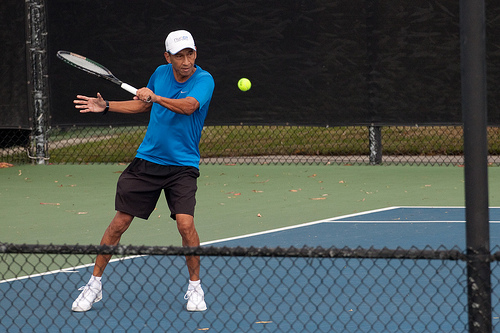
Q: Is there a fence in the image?
A: Yes, there is a fence.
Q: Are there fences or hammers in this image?
A: Yes, there is a fence.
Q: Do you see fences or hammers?
A: Yes, there is a fence.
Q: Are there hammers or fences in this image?
A: Yes, there is a fence.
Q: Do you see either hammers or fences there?
A: Yes, there is a fence.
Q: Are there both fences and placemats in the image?
A: No, there is a fence but no placemats.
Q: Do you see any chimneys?
A: No, there are no chimneys.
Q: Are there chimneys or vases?
A: No, there are no chimneys or vases.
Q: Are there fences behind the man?
A: Yes, there is a fence behind the man.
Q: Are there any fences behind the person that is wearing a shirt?
A: Yes, there is a fence behind the man.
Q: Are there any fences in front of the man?
A: No, the fence is behind the man.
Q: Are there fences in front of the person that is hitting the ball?
A: No, the fence is behind the man.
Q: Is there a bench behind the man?
A: No, there is a fence behind the man.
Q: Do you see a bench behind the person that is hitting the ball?
A: No, there is a fence behind the man.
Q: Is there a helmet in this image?
A: No, there are no helmets.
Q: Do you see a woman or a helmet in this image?
A: No, there are no helmets or women.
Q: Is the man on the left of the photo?
A: Yes, the man is on the left of the image.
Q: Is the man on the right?
A: No, the man is on the left of the image.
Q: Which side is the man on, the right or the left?
A: The man is on the left of the image.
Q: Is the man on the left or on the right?
A: The man is on the left of the image.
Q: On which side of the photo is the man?
A: The man is on the left of the image.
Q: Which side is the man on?
A: The man is on the left of the image.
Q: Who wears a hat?
A: The man wears a hat.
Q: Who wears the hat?
A: The man wears a hat.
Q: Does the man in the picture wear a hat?
A: Yes, the man wears a hat.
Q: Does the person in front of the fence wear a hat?
A: Yes, the man wears a hat.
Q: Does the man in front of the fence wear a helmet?
A: No, the man wears a hat.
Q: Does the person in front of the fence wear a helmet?
A: No, the man wears a hat.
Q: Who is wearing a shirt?
A: The man is wearing a shirt.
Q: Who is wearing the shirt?
A: The man is wearing a shirt.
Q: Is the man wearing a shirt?
A: Yes, the man is wearing a shirt.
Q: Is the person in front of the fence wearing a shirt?
A: Yes, the man is wearing a shirt.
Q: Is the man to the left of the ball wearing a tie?
A: No, the man is wearing a shirt.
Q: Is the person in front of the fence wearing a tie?
A: No, the man is wearing a shirt.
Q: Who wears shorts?
A: The man wears shorts.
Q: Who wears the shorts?
A: The man wears shorts.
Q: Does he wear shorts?
A: Yes, the man wears shorts.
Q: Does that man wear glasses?
A: No, the man wears shorts.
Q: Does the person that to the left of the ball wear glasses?
A: No, the man wears shorts.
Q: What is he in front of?
A: The man is in front of the fence.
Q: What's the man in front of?
A: The man is in front of the fence.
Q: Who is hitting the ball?
A: The man is hitting the ball.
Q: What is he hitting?
A: The man is hitting the ball.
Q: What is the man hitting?
A: The man is hitting the ball.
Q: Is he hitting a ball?
A: Yes, the man is hitting a ball.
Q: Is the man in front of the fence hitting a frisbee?
A: No, the man is hitting a ball.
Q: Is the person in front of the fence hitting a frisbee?
A: No, the man is hitting a ball.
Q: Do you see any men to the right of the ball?
A: No, the man is to the left of the ball.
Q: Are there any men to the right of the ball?
A: No, the man is to the left of the ball.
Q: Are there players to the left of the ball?
A: No, there is a man to the left of the ball.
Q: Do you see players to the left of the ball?
A: No, there is a man to the left of the ball.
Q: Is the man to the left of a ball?
A: Yes, the man is to the left of a ball.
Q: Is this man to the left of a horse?
A: No, the man is to the left of a ball.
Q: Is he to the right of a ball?
A: No, the man is to the left of a ball.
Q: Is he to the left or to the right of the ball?
A: The man is to the left of the ball.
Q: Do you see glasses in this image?
A: No, there are no glasses.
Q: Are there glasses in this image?
A: No, there are no glasses.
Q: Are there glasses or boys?
A: No, there are no glasses or boys.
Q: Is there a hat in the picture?
A: Yes, there is a hat.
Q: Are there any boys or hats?
A: Yes, there is a hat.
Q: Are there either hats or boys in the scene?
A: Yes, there is a hat.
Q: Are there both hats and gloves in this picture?
A: No, there is a hat but no gloves.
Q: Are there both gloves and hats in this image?
A: No, there is a hat but no gloves.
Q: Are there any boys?
A: No, there are no boys.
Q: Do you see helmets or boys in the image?
A: No, there are no boys or helmets.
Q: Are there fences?
A: Yes, there is a fence.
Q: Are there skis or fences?
A: Yes, there is a fence.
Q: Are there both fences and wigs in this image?
A: No, there is a fence but no wigs.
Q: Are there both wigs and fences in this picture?
A: No, there is a fence but no wigs.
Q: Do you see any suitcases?
A: No, there are no suitcases.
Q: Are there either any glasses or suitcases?
A: No, there are no suitcases or glasses.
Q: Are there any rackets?
A: Yes, there is a racket.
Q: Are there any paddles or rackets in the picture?
A: Yes, there is a racket.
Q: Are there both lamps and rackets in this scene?
A: No, there is a racket but no lamps.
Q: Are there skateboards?
A: No, there are no skateboards.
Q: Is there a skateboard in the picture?
A: No, there are no skateboards.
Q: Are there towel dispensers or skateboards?
A: No, there are no skateboards or towel dispensers.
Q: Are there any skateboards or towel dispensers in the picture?
A: No, there are no skateboards or towel dispensers.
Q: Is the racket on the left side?
A: Yes, the racket is on the left of the image.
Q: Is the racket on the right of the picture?
A: No, the racket is on the left of the image.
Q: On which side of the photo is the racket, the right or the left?
A: The racket is on the left of the image.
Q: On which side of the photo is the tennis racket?
A: The tennis racket is on the left of the image.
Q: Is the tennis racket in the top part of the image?
A: Yes, the tennis racket is in the top of the image.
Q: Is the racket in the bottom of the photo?
A: No, the racket is in the top of the image.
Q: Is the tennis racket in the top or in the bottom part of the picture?
A: The tennis racket is in the top of the image.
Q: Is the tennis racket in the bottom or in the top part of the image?
A: The tennis racket is in the top of the image.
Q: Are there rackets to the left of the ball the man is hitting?
A: Yes, there is a racket to the left of the ball.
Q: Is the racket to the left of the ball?
A: Yes, the racket is to the left of the ball.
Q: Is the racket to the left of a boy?
A: No, the racket is to the left of the ball.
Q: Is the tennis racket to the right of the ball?
A: No, the tennis racket is to the left of the ball.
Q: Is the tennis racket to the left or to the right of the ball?
A: The tennis racket is to the left of the ball.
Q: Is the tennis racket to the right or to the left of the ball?
A: The tennis racket is to the left of the ball.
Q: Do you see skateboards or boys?
A: No, there are no boys or skateboards.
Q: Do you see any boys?
A: No, there are no boys.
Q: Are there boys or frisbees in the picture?
A: No, there are no boys or frisbees.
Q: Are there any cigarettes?
A: No, there are no cigarettes.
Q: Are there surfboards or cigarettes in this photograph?
A: No, there are no cigarettes or surfboards.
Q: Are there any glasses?
A: No, there are no glasses.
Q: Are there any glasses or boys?
A: No, there are no glasses or boys.